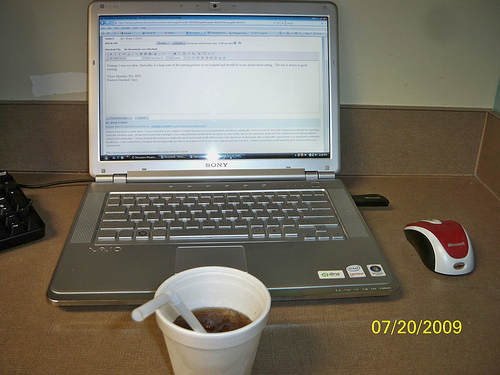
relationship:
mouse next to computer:
[403, 217, 477, 276] [46, 3, 402, 308]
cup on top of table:
[151, 264, 271, 374] [0, 174, 500, 374]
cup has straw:
[151, 264, 271, 374] [130, 291, 210, 336]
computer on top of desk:
[46, 3, 402, 308] [0, 174, 500, 374]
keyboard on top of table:
[0, 173, 46, 252] [0, 174, 500, 374]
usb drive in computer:
[350, 194, 388, 206] [46, 3, 402, 308]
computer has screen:
[46, 3, 402, 308] [99, 14, 331, 156]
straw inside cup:
[130, 291, 210, 336] [151, 264, 271, 374]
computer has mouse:
[46, 3, 402, 308] [403, 217, 477, 276]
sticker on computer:
[314, 268, 344, 279] [46, 3, 402, 308]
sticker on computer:
[345, 264, 366, 279] [46, 3, 402, 308]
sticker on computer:
[366, 263, 386, 279] [46, 3, 402, 308]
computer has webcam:
[46, 3, 402, 308] [209, 0, 219, 10]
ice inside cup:
[205, 307, 239, 327] [151, 264, 271, 374]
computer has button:
[46, 3, 402, 308] [97, 230, 117, 240]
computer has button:
[46, 3, 402, 308] [118, 230, 134, 240]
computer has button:
[46, 3, 402, 308] [134, 230, 150, 240]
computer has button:
[46, 3, 402, 308] [248, 225, 266, 237]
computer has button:
[46, 3, 402, 308] [266, 226, 282, 237]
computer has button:
[46, 3, 402, 308] [283, 226, 298, 235]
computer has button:
[46, 3, 402, 308] [98, 220, 137, 229]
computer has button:
[46, 3, 402, 308] [136, 221, 152, 229]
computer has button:
[46, 3, 402, 308] [154, 221, 167, 230]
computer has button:
[46, 3, 402, 308] [170, 220, 184, 230]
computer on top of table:
[46, 3, 402, 308] [0, 174, 500, 374]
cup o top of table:
[151, 264, 271, 374] [0, 174, 500, 374]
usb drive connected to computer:
[350, 194, 388, 206] [46, 3, 402, 308]